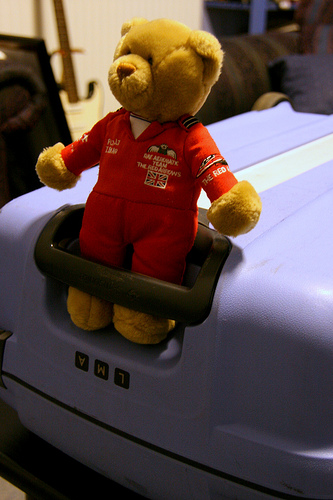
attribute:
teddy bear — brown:
[33, 15, 262, 287]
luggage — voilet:
[223, 257, 331, 443]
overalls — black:
[63, 108, 238, 280]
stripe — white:
[228, 140, 318, 182]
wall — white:
[33, 3, 189, 101]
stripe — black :
[0, 369, 304, 499]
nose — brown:
[116, 61, 135, 80]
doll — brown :
[74, 6, 291, 263]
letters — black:
[57, 347, 132, 391]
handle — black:
[29, 198, 243, 332]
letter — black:
[93, 358, 109, 381]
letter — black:
[111, 367, 129, 386]